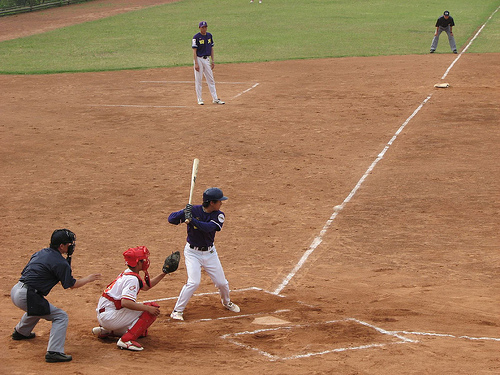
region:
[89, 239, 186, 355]
catcher wearing uniform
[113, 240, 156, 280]
catcher wearing red helmet and mask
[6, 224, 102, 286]
umpire wearing black shirt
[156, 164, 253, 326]
batter wearing uniform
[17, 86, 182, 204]
brown dirt on baseball field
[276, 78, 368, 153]
brown dirt on baseball field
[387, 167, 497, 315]
brown dirt on baseball field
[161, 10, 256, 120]
young man wearing blue shirt and white pants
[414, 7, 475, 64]
umpire wearing black shirt and gray pants for uniform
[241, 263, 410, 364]
brown home plate with white powder stripes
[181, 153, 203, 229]
A wooden baseball bat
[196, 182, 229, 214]
A blue baseball helmet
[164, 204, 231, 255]
A blue baseball uniform top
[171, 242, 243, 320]
White baseball uniform pants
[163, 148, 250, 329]
A baseball player getting ready to swing the bat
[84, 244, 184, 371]
The catcher waiting to catch the ball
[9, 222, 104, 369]
The umpire ready to make the call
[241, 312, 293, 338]
The baseball field's home base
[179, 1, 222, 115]
A baseball player in the outfield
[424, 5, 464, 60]
A baseball referee waiting to make a call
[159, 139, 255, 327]
Baseball player bat ready strike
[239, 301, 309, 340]
Home plate clearly marked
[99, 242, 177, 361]
Catcher prepares catch ball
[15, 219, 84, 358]
Umpire calls ball status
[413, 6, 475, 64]
Outfielder near third base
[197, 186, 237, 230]
Safety helmet batter's head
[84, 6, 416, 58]
Outfield well tended grass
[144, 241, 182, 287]
Left hand catcher's mitt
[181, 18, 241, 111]
Just standing watching outcome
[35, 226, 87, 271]
Face mask protects umpire face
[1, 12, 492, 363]
Photo taken on a baseball field.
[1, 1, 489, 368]
Men playing baseball.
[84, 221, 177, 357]
Red equipment on the catcher.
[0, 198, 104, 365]
Umpire behind the catcher.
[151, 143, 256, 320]
Right-handed batter.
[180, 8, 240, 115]
Third base coach.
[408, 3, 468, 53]
Third base umpire.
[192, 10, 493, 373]
White lines on the field.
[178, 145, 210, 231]
Wooden baseball bat in the man's hands.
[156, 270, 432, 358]
Batter's box outlined in white.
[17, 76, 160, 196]
brown dirt of baseball field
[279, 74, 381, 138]
brown dirt of baseball field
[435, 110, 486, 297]
brown dirt of baseball field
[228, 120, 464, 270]
brown dirt with white stripe of baseball field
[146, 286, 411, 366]
brown dirt with white stripe of baseball field home plate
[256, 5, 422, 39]
green field of baseball field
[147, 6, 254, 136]
young man in gray pants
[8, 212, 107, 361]
umpire in black shirt and gray pants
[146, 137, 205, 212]
batter holding tan wooden bat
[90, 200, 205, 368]
catcher ready to catch ball